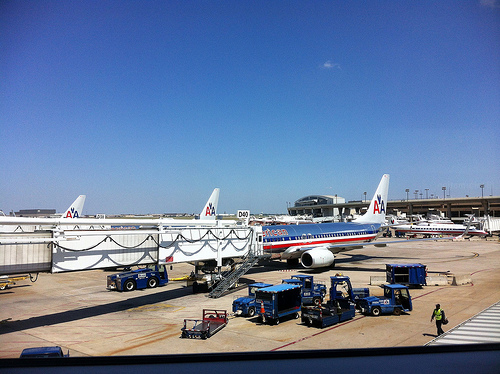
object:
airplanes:
[48, 171, 394, 266]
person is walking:
[428, 302, 448, 334]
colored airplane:
[255, 173, 390, 272]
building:
[282, 192, 495, 240]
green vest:
[433, 309, 443, 322]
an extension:
[3, 226, 256, 270]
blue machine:
[254, 282, 302, 322]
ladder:
[206, 250, 263, 298]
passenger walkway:
[283, 255, 498, 350]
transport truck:
[358, 281, 414, 316]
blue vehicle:
[298, 270, 353, 326]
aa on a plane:
[372, 197, 387, 215]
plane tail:
[357, 173, 389, 221]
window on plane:
[283, 238, 285, 240]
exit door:
[256, 233, 265, 256]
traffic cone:
[179, 277, 194, 283]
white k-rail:
[1, 211, 251, 276]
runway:
[5, 230, 499, 360]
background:
[6, 112, 499, 277]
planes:
[118, 174, 399, 275]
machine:
[105, 258, 167, 289]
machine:
[293, 275, 327, 306]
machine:
[356, 282, 412, 314]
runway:
[2, 272, 497, 362]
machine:
[179, 306, 231, 341]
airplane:
[392, 214, 469, 235]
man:
[429, 301, 449, 336]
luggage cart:
[384, 261, 428, 288]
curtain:
[406, 266, 424, 281]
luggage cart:
[256, 280, 303, 322]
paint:
[265, 221, 384, 232]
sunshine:
[5, 64, 498, 359]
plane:
[198, 185, 219, 217]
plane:
[58, 191, 87, 221]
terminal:
[284, 192, 498, 221]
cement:
[0, 233, 497, 355]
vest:
[435, 309, 442, 320]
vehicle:
[230, 280, 274, 317]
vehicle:
[299, 272, 356, 327]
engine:
[296, 247, 337, 272]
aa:
[65, 209, 80, 219]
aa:
[204, 204, 218, 216]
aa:
[371, 200, 388, 214]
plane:
[262, 171, 391, 270]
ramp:
[2, 209, 252, 278]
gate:
[2, 209, 257, 274]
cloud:
[317, 51, 344, 77]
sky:
[2, 2, 482, 219]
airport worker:
[430, 301, 449, 335]